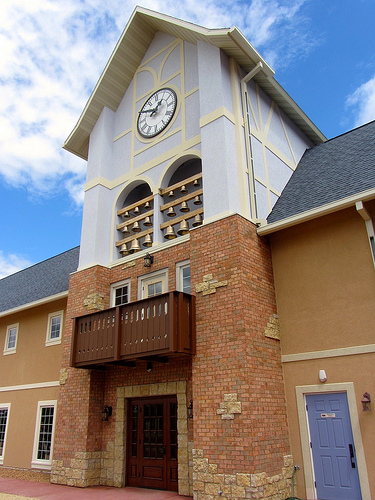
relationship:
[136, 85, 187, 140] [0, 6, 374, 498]
clock on building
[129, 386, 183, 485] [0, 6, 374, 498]
door on building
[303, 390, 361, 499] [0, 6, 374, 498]
door on building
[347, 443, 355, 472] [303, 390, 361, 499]
handle of door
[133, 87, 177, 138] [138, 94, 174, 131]
clock with black numbers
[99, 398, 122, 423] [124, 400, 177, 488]
light on left of burgundy door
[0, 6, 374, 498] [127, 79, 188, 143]
building has clock on building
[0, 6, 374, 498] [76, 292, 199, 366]
building has brown balcony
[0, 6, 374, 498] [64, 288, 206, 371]
building has brown balcony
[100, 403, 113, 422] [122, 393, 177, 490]
black light next to door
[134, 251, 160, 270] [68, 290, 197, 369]
lamp above balcony above balcony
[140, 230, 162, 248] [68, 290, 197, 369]
gold bell above balcony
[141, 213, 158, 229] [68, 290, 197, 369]
"gold bell above balcony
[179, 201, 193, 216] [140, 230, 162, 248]
gold bell next to gold bell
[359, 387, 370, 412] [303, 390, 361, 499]
"small lamp next to door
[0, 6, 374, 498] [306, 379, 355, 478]
building has blue door on buildin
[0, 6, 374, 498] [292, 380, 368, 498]
building has blue door on buildin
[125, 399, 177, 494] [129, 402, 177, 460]
"brown door has windows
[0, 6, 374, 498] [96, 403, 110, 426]
building has black light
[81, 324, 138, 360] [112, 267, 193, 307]
brown deck below windows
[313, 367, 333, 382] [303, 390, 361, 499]
white light above door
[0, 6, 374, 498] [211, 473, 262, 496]
building has tan bricks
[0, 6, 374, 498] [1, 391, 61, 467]
building has two windows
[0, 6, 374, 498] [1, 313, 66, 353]
building has two windows